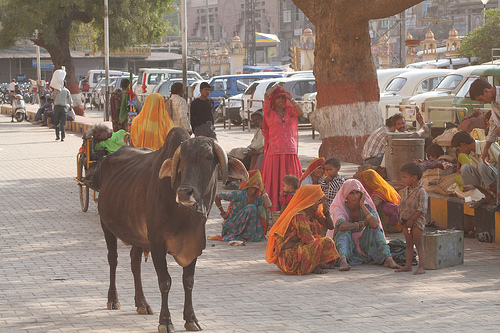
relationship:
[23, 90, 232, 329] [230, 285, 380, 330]
cow on sidewalk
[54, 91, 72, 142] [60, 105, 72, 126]
man holds package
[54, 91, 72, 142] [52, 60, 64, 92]
man carries bag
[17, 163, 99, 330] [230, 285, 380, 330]
shadow on sidewalk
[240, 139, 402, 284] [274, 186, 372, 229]
women wear saris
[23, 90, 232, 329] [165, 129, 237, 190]
cow has horns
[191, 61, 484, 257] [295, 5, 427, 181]
people under tree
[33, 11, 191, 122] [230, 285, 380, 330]
poles on sidewalk